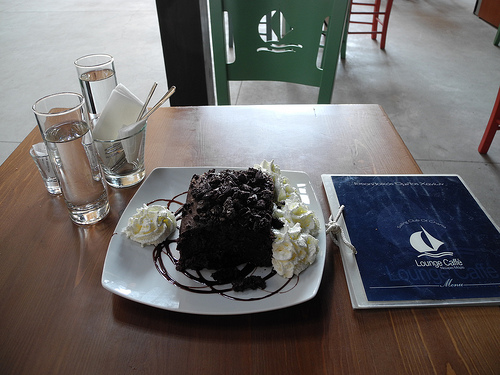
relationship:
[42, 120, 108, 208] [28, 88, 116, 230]
water inside of glass